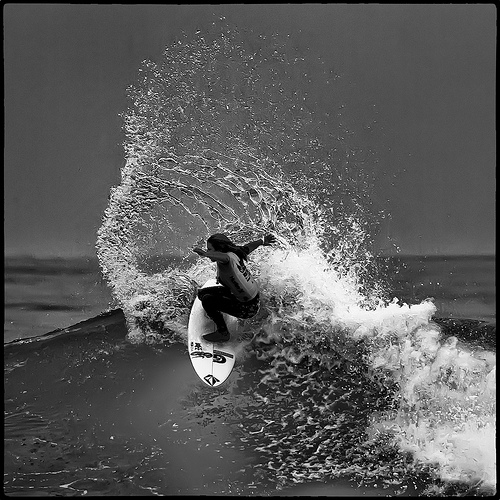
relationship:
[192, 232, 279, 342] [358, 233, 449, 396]
person surfing in ocean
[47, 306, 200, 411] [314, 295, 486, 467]
waves in ocean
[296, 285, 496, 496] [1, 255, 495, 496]
waves in ocean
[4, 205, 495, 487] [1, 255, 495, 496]
waves in ocean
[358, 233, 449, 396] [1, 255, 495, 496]
ocean in ocean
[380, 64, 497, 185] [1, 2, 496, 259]
clouds in sky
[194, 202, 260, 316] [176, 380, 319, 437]
rider in water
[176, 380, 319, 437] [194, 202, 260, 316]
water above rider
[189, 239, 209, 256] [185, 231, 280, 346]
hands to side of woman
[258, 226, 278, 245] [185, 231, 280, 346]
hands to side of woman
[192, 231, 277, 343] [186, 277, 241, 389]
woman on surfboard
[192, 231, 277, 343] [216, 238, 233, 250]
woman with hair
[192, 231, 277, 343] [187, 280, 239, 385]
woman on board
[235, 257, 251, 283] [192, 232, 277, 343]
advertising on wet suit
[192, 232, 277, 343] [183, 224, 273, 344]
wet suit of woman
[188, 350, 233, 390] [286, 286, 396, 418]
board pointed toward water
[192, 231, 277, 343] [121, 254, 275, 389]
woman on surfboard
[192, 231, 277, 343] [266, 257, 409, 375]
woman surfing a wave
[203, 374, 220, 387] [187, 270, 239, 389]
logo on surfboard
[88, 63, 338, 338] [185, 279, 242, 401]
splash off a surfboard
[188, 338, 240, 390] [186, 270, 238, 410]
logo on surfboard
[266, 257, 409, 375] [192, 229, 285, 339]
wave crashing near surfer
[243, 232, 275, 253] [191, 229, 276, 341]
arm of a surfer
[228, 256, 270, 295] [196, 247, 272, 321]
logo on back of a wetsuit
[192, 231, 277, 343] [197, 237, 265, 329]
woman surfing a wave wet suit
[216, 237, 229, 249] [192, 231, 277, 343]
hair on woman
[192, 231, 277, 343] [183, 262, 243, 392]
woman on surfboard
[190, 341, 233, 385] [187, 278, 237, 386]
logos on surfboard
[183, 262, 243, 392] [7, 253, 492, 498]
surfboard in water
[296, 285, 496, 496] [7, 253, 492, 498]
waves in water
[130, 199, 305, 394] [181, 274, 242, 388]
person surfing on board